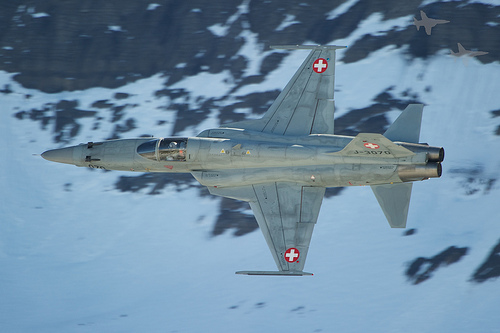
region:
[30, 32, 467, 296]
fighter plane flying in the sky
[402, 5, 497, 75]
2 planes drawn in behind fighter plane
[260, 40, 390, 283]
3 red crosses on the plane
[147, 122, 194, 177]
one pilot in the plane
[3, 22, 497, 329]
plane flying next to mountain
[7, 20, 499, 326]
lots of snow on the mountain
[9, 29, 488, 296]
silver fighter plane with red crosses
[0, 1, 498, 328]
snow and rock on ground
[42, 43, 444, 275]
top of military jet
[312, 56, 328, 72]
red circle with white cross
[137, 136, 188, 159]
glass dome of cockpit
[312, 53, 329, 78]
small red circle with a white cross inside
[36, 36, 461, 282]
gray military plane in flight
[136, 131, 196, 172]
person in the cockpit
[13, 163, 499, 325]
white snow on the ground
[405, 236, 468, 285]
bit of ground that snow isn't covering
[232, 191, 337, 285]
triangular wing of the plane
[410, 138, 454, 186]
two silver jets on the tail of the plane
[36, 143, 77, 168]
pointed nose of the plane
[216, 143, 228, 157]
tiny triangle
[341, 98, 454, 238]
back end of the plane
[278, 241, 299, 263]
red and white on left wing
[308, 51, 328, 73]
right wing with red and white cross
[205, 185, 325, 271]
left wing of airplane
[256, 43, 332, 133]
right wing of airplane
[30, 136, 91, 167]
nose of airplane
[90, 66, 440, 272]
airplane flying in the air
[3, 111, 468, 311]
snow covered landscape under plane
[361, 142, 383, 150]
red cross on control yaw vertical stabilizer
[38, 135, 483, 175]
body of flying airplane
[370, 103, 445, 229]
tail of flying airplane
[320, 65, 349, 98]
edge of a wing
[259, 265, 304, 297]
edge of a wing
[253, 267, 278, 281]
part of a missile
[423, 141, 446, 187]
part of a the back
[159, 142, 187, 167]
part of a cockpit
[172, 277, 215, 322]
part of a snow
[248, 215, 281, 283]
edge of a wing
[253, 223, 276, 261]
edge of a wing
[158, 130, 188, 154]
part of a cockpit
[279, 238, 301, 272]
the jet has red cross logo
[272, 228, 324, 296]
the jet has red cross logo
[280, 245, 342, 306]
the jet has red cross logo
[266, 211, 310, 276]
the jet has red cross logo